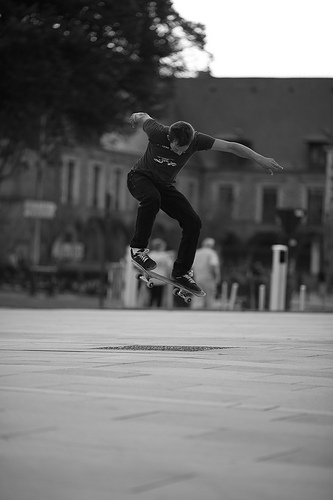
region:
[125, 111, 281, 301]
a guy riding on a skateboard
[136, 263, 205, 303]
a boy's skateboard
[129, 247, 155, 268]
a guy's right shoe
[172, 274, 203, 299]
a guy's left shoe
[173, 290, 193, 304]
a skateboard's front wheels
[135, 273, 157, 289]
a skateboard's rear wheels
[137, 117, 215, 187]
a skateboarder's shirt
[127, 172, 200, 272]
a skateboarder's pants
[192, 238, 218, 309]
a man standing by a street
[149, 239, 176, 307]
a woman standing in the street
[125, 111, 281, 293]
skateboarder inb the air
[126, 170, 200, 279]
black pants of skateboarder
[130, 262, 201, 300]
black skateboard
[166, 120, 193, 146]
short black hair of skateboard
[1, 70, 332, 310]
building in the back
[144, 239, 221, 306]
two people walking in a park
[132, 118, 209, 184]
black t-shirt of skateboarder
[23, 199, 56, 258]
signboard in pole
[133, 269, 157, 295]
two front wheels of skateboard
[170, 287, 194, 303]
two back wheels of skateboard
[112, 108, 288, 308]
Young man skateboarding.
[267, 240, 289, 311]
silver colored container in the background.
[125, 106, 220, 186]
Young man wearing a t-shirt.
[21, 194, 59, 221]
Sign on the post.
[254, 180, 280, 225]
Window in the building.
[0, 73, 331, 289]
Building in the background.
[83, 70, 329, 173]
Roof on the building.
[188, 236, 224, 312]
Older man walking in the background.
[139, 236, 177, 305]
Older woman walking in the background.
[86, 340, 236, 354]
Grate in the pavement.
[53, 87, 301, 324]
a kid on a skateboard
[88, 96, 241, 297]
he is doing a stunt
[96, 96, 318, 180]
his arms are extended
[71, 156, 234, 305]
he is lifting the board off of the ground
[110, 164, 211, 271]
he is wearing dark colored pants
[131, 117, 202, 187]
he has on a t-shirt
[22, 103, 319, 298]
the background behind the skateboarder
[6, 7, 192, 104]
trees above the skater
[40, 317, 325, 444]
concrete ground below the skater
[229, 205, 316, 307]
objects in the background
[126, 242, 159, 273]
Foot Turned to the side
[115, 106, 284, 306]
Skateboarder performing a trick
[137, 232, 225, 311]
Blurry old couple in the background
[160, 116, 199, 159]
Man's head is pointing down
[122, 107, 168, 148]
Right arm extending backwards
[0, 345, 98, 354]
Shadow being cast from skateboarder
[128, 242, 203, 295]
Pair of black and white tennis shoes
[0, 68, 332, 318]
Building in the background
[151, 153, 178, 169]
White logo on man's shirt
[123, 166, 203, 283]
Black Denim Jeans